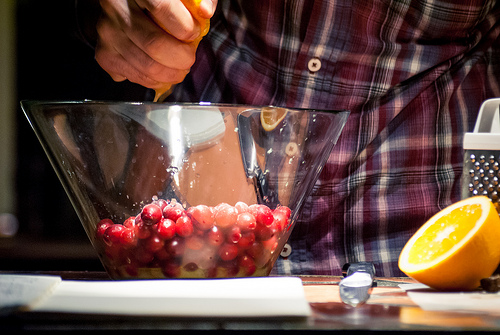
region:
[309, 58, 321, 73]
The button is round.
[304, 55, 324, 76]
The button is white.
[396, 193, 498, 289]
The orange is cut in half.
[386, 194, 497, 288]
The fruit is an orange.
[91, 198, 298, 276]
The grapes are red in color.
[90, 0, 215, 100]
The man is squeezing an orange.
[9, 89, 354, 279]
The grapes are in a clear bowl.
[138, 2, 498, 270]
front of plaid shirt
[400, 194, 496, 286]
half of sliced orange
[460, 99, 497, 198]
grater with white handle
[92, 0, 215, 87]
hand squeezing slice of fruit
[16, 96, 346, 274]
glass bowl of berries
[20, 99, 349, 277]
light reflection on glass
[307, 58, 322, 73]
round button of shirt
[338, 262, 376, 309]
knife with black handle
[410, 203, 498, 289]
skin on exterior of fruit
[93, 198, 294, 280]
pile of cranberries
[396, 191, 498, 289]
cut half of an orange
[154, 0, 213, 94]
squeezed cut half of an orange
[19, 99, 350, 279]
large clear glass mixing bowl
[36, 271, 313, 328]
white cutting board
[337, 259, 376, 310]
clear plastic handled knife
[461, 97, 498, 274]
grey plastic and silver metal grater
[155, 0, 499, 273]
reddish purple plaid patterned shirt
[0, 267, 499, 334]
wooden kitchen counter top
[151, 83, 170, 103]
fresh squeezed orange juice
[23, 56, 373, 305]
this is a glass bowl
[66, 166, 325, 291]
these are a bunch of cherries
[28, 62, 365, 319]
cherries in inside glass bowl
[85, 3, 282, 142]
person is squeezing a orange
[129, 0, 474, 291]
person wearing a plaid shirt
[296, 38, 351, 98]
button on plaid shirt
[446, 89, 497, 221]
a metal food grater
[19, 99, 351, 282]
A large glass bowl of berries.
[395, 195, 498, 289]
A half an orange.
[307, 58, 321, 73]
Tan round button above a bowl.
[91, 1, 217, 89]
A right man's hand.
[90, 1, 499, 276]
A man in a striped shirt squeezing fruit in his right hand.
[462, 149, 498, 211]
The silver part of a cheese grater.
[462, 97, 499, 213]
A white and silver cheese grater.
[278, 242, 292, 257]
Bottom most button on a shirt.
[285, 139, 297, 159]
Tan button you can see through a bowl.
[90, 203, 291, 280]
All red berries inside a bowl.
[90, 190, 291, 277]
cranberries in a clear bowl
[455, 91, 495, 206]
metal grater with white handle